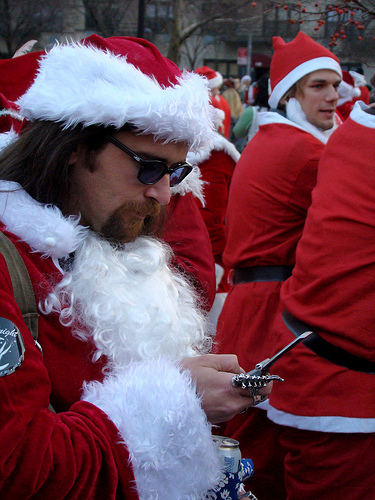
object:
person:
[265, 99, 375, 500]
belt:
[280, 304, 375, 374]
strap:
[0, 231, 37, 343]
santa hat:
[337, 70, 360, 98]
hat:
[13, 32, 215, 149]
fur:
[15, 38, 210, 155]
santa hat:
[267, 30, 341, 109]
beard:
[298, 101, 334, 131]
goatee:
[101, 199, 164, 245]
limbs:
[320, 5, 367, 49]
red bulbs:
[340, 35, 346, 40]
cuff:
[188, 132, 241, 164]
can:
[217, 439, 241, 474]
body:
[269, 111, 374, 392]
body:
[210, 118, 328, 373]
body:
[0, 207, 177, 500]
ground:
[281, 95, 312, 125]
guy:
[208, 30, 342, 374]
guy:
[0, 34, 272, 500]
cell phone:
[244, 331, 312, 377]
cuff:
[82, 359, 226, 500]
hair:
[0, 118, 136, 209]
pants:
[279, 426, 375, 499]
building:
[0, 0, 375, 102]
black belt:
[231, 262, 296, 285]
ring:
[231, 372, 285, 396]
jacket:
[0, 181, 225, 500]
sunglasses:
[108, 126, 194, 186]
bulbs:
[233, 357, 269, 390]